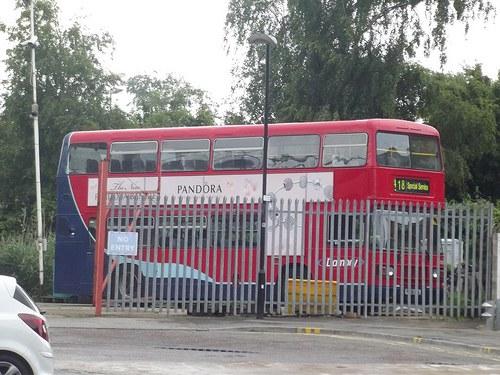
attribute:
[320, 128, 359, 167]
window — clear, glass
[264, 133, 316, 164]
glass window — clear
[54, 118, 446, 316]
bus — red, white, blue, yellow, large, silver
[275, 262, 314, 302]
tire — black, rubber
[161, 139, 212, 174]
window — clear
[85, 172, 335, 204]
sign — white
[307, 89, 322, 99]
leaves — green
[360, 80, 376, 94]
leaves — green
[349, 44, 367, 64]
leaves — green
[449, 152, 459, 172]
leaves — green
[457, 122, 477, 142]
leaves — green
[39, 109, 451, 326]
bus — red, white, blue, black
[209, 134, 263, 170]
window — clear, glass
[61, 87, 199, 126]
leaves — green